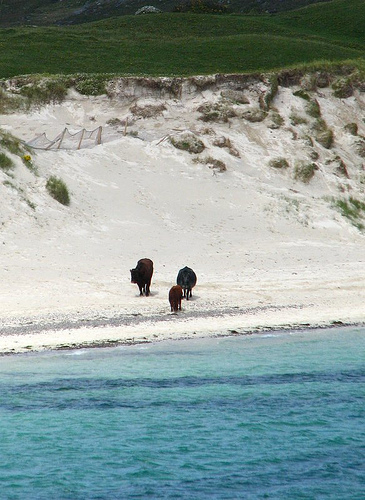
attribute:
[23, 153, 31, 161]
ball — yellow, black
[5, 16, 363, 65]
grass — green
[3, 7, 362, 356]
hillside — covered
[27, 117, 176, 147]
fence — white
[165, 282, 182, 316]
cow — standing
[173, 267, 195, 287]
black cow — big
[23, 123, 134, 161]
fence — falling, down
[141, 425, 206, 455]
water — blue-green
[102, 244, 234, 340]
cow — standing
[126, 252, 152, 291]
cow — big, brown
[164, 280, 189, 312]
cow — small, brown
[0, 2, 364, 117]
grass — short, green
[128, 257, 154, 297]
bison — brown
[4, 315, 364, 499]
sea — blue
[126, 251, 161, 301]
cow — standing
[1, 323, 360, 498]
water — blue-green, ripply, blue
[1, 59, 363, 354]
ground — snowy